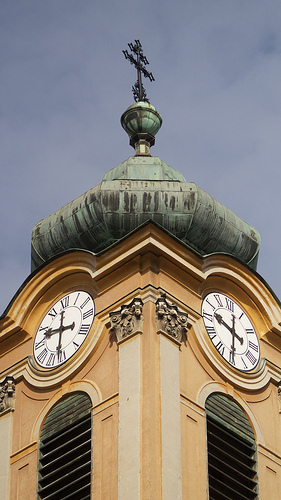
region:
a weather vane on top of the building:
[92, 21, 183, 111]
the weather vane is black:
[89, 32, 188, 105]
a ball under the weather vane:
[93, 91, 174, 162]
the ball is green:
[98, 88, 179, 151]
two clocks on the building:
[6, 266, 268, 391]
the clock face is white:
[25, 280, 105, 364]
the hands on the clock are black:
[36, 302, 78, 344]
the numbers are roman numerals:
[15, 281, 107, 370]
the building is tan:
[45, 286, 265, 496]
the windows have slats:
[21, 387, 97, 492]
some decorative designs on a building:
[101, 297, 149, 346]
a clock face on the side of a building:
[18, 293, 107, 373]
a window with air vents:
[28, 397, 111, 493]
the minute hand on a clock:
[54, 309, 67, 361]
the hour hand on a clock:
[37, 321, 77, 337]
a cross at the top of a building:
[97, 29, 188, 157]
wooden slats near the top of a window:
[201, 383, 262, 454]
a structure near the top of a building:
[28, 157, 268, 270]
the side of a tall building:
[162, 395, 203, 493]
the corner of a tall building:
[116, 206, 179, 320]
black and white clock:
[28, 295, 97, 372]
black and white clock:
[199, 289, 267, 368]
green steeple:
[121, 92, 174, 157]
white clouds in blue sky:
[11, 11, 40, 47]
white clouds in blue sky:
[16, 78, 43, 115]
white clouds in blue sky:
[15, 110, 44, 158]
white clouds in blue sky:
[20, 134, 69, 176]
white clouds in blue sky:
[70, 26, 99, 77]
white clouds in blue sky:
[191, 26, 210, 60]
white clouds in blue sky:
[188, 42, 243, 117]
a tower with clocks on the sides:
[0, 38, 279, 498]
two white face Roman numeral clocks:
[32, 289, 259, 370]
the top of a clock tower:
[25, 37, 264, 217]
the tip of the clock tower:
[120, 38, 156, 102]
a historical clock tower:
[0, 38, 279, 498]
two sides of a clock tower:
[0, 218, 280, 497]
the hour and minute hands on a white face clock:
[213, 311, 244, 355]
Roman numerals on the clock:
[33, 291, 94, 368]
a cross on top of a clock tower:
[120, 38, 163, 156]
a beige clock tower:
[1, 218, 279, 498]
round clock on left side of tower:
[32, 288, 96, 372]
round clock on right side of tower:
[200, 290, 261, 371]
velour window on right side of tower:
[203, 391, 258, 498]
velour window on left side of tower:
[36, 390, 94, 497]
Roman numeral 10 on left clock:
[37, 323, 49, 333]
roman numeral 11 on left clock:
[46, 305, 57, 319]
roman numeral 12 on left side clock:
[57, 295, 70, 309]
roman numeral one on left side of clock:
[72, 291, 80, 306]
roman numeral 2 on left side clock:
[78, 296, 89, 307]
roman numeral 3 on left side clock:
[80, 308, 94, 320]